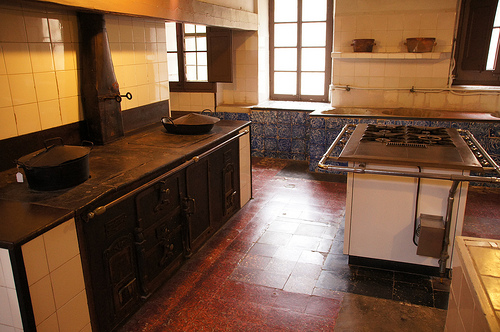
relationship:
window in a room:
[277, 0, 349, 93] [25, 0, 497, 310]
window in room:
[299, 21, 327, 50] [1, 0, 496, 330]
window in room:
[275, 47, 297, 70] [1, 0, 496, 330]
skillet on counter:
[22, 142, 90, 184] [0, 90, 262, 266]